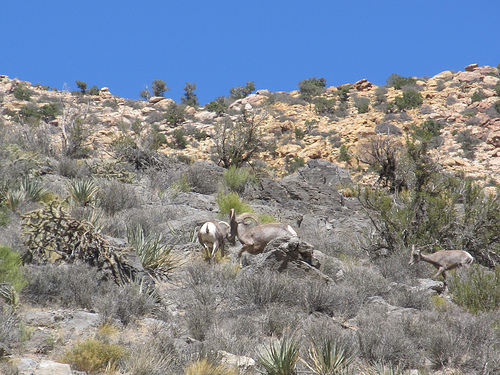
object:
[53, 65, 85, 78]
sky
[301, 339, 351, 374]
plant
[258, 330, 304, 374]
leaves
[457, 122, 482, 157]
wall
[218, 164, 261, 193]
bush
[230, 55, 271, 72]
sky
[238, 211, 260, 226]
horns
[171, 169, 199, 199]
grass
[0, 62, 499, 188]
mountain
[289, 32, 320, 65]
white clouds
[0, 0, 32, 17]
blue sky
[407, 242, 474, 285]
animal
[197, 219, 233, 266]
animal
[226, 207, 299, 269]
animal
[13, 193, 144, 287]
tree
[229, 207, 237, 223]
horns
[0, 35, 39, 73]
sky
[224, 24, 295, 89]
cloud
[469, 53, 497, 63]
sky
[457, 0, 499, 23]
clouds sky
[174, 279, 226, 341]
bush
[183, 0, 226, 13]
sky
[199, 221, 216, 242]
butt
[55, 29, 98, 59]
sky